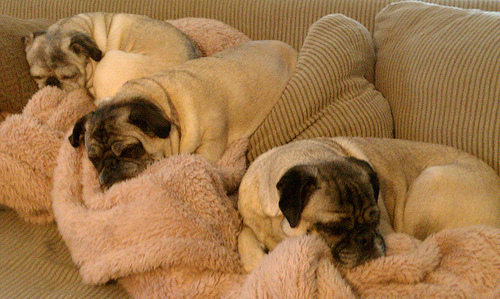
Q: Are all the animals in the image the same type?
A: Yes, all the animals are dogs.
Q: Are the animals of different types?
A: No, all the animals are dogs.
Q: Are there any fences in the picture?
A: No, there are no fences.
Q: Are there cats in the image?
A: No, there are no cats.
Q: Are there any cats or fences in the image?
A: No, there are no cats or fences.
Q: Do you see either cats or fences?
A: No, there are no cats or fences.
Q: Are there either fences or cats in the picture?
A: No, there are no cats or fences.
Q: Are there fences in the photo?
A: No, there are no fences.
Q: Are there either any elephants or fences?
A: No, there are no fences or elephants.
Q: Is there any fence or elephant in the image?
A: No, there are no fences or elephants.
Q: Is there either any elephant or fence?
A: No, there are no fences or elephants.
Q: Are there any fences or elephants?
A: No, there are no fences or elephants.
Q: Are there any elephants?
A: No, there are no elephants.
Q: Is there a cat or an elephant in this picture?
A: No, there are no elephants or cats.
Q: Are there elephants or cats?
A: No, there are no elephants or cats.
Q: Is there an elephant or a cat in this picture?
A: No, there are no elephants or cats.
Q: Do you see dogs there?
A: Yes, there is a dog.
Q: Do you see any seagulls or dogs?
A: Yes, there is a dog.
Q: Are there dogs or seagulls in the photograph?
A: Yes, there is a dog.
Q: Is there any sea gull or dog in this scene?
A: Yes, there is a dog.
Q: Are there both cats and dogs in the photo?
A: No, there is a dog but no cats.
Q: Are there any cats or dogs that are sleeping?
A: Yes, the dog is sleeping.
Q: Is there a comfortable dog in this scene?
A: Yes, there is a comfortable dog.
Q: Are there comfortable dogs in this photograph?
A: Yes, there is a comfortable dog.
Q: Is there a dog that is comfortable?
A: Yes, there is a dog that is comfortable.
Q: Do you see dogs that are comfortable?
A: Yes, there is a dog that is comfortable.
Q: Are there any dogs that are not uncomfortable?
A: Yes, there is an comfortable dog.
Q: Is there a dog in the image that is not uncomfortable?
A: Yes, there is an comfortable dog.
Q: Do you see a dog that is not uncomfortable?
A: Yes, there is an comfortable dog.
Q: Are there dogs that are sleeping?
A: Yes, there is a dog that is sleeping.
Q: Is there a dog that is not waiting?
A: Yes, there is a dog that is sleeping.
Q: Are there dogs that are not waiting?
A: Yes, there is a dog that is sleeping.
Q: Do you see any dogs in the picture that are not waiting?
A: Yes, there is a dog that is sleeping .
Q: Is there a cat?
A: No, there are no cats.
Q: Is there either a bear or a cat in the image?
A: No, there are no cats or bears.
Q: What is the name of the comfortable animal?
A: The animal is a dog.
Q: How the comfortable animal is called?
A: The animal is a dog.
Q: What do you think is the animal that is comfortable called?
A: The animal is a dog.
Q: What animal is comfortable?
A: The animal is a dog.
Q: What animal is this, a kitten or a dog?
A: This is a dog.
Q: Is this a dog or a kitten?
A: This is a dog.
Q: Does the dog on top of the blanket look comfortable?
A: Yes, the dog is comfortable.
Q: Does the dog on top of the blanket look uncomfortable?
A: No, the dog is comfortable.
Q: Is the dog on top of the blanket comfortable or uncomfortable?
A: The dog is comfortable.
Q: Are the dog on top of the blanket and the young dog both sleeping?
A: Yes, both the dog and the dog are sleeping.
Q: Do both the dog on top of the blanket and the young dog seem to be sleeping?
A: Yes, both the dog and the dog are sleeping.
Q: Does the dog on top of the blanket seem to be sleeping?
A: Yes, the dog is sleeping.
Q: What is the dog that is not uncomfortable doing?
A: The dog is sleeping.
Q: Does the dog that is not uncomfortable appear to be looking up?
A: No, the dog is sleeping.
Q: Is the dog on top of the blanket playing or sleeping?
A: The dog is sleeping.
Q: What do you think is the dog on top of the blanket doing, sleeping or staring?
A: The dog is sleeping.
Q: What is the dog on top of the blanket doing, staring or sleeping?
A: The dog is sleeping.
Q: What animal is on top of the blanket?
A: The animal is a dog.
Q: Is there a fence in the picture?
A: No, there are no fences.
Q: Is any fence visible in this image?
A: No, there are no fences.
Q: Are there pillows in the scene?
A: Yes, there is a pillow.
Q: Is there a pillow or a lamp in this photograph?
A: Yes, there is a pillow.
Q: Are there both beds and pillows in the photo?
A: No, there is a pillow but no beds.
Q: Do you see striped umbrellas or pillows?
A: Yes, there is a striped pillow.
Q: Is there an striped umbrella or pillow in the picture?
A: Yes, there is a striped pillow.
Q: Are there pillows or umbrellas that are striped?
A: Yes, the pillow is striped.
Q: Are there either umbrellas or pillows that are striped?
A: Yes, the pillow is striped.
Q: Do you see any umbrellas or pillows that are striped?
A: Yes, the pillow is striped.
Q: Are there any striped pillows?
A: Yes, there is a striped pillow.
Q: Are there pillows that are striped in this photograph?
A: Yes, there is a striped pillow.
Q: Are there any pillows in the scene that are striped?
A: Yes, there is a pillow that is striped.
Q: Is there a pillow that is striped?
A: Yes, there is a pillow that is striped.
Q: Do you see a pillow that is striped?
A: Yes, there is a pillow that is striped.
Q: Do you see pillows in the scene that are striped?
A: Yes, there is a pillow that is striped.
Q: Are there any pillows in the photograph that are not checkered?
A: Yes, there is a striped pillow.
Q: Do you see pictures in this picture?
A: No, there are no pictures.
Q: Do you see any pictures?
A: No, there are no pictures.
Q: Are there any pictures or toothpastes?
A: No, there are no pictures or toothpastes.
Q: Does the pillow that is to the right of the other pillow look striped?
A: Yes, the pillow is striped.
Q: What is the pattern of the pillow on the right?
A: The pillow is striped.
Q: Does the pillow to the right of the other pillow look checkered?
A: No, the pillow is striped.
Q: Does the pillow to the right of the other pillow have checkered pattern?
A: No, the pillow is striped.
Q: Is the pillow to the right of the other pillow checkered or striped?
A: The pillow is striped.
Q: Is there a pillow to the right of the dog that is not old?
A: Yes, there is a pillow to the right of the dog.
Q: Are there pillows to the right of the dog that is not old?
A: Yes, there is a pillow to the right of the dog.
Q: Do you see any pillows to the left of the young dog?
A: No, the pillow is to the right of the dog.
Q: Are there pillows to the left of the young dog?
A: No, the pillow is to the right of the dog.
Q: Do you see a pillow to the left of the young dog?
A: No, the pillow is to the right of the dog.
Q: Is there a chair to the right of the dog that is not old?
A: No, there is a pillow to the right of the dog.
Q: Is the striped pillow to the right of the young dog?
A: Yes, the pillow is to the right of the dog.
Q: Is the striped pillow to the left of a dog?
A: No, the pillow is to the right of a dog.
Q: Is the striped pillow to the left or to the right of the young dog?
A: The pillow is to the right of the dog.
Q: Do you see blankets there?
A: Yes, there is a blanket.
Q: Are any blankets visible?
A: Yes, there is a blanket.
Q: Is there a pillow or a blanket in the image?
A: Yes, there is a blanket.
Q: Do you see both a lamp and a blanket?
A: No, there is a blanket but no lamps.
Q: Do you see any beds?
A: No, there are no beds.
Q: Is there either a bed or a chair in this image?
A: No, there are no beds or chairs.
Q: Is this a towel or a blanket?
A: This is a blanket.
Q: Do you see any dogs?
A: Yes, there is a dog.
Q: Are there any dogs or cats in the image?
A: Yes, there is a dog.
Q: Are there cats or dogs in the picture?
A: Yes, there is a dog.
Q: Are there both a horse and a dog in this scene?
A: No, there is a dog but no horses.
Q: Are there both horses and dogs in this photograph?
A: No, there is a dog but no horses.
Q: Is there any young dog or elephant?
A: Yes, there is a young dog.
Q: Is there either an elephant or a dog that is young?
A: Yes, the dog is young.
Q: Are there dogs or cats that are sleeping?
A: Yes, the dog is sleeping.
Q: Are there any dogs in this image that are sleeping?
A: Yes, there is a dog that is sleeping.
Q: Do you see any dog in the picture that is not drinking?
A: Yes, there is a dog that is sleeping .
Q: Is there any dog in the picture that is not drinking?
A: Yes, there is a dog that is sleeping.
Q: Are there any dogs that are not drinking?
A: Yes, there is a dog that is sleeping.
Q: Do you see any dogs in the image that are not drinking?
A: Yes, there is a dog that is sleeping .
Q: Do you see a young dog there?
A: Yes, there is a young dog.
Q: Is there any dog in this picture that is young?
A: Yes, there is a dog that is young.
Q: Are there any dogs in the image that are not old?
A: Yes, there is an young dog.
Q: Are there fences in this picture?
A: No, there are no fences.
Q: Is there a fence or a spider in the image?
A: No, there are no fences or spiders.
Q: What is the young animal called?
A: The animal is a dog.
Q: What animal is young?
A: The animal is a dog.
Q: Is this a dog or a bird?
A: This is a dog.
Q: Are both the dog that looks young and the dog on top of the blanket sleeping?
A: Yes, both the dog and the dog are sleeping.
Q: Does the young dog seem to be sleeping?
A: Yes, the dog is sleeping.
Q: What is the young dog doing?
A: The dog is sleeping.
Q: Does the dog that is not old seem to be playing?
A: No, the dog is sleeping.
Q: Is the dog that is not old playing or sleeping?
A: The dog is sleeping.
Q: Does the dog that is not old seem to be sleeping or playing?
A: The dog is sleeping.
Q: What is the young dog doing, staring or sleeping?
A: The dog is sleeping.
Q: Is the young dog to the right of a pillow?
A: No, the dog is to the left of a pillow.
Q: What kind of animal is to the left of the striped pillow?
A: The animal is a dog.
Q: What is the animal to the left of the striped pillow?
A: The animal is a dog.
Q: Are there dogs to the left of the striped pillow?
A: Yes, there is a dog to the left of the pillow.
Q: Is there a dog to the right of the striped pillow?
A: No, the dog is to the left of the pillow.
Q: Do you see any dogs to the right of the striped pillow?
A: No, the dog is to the left of the pillow.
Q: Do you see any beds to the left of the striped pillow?
A: No, there is a dog to the left of the pillow.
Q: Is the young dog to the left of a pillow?
A: Yes, the dog is to the left of a pillow.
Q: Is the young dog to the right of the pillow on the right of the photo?
A: No, the dog is to the left of the pillow.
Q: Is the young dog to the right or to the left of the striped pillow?
A: The dog is to the left of the pillow.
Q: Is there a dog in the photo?
A: Yes, there is a dog.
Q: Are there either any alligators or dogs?
A: Yes, there is a dog.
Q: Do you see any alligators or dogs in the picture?
A: Yes, there is a dog.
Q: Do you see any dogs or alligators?
A: Yes, there is a dog.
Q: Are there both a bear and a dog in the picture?
A: No, there is a dog but no bears.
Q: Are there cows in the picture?
A: No, there are no cows.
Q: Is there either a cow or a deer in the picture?
A: No, there are no cows or deer.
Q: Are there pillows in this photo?
A: Yes, there is a pillow.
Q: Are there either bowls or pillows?
A: Yes, there is a pillow.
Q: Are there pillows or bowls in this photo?
A: Yes, there is a pillow.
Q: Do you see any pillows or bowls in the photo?
A: Yes, there is a pillow.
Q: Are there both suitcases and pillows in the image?
A: No, there is a pillow but no suitcases.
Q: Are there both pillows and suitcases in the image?
A: No, there is a pillow but no suitcases.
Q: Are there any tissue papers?
A: No, there are no tissue papers.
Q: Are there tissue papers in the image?
A: No, there are no tissue papers.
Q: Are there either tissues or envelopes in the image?
A: No, there are no tissues or envelopes.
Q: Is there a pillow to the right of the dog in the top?
A: Yes, there is a pillow to the right of the dog.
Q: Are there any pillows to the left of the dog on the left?
A: No, the pillow is to the right of the dog.